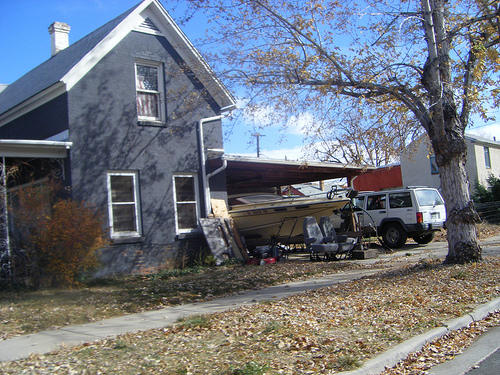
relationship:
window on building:
[132, 62, 171, 125] [0, 2, 240, 294]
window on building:
[104, 168, 138, 241] [0, 2, 240, 294]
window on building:
[114, 44, 181, 132] [0, 0, 381, 286]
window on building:
[480, 143, 497, 173] [0, 0, 381, 286]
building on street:
[0, 0, 499, 288] [0, 1, 500, 372]